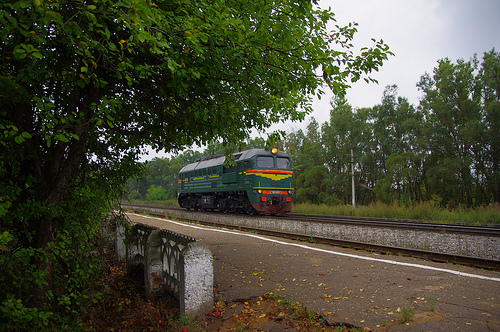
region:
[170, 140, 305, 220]
Locomotive of a freight train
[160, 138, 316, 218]
Locomotive for a passenger train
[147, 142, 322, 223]
Locomotive not pulling any cars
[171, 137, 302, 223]
Locomotive going down the tracks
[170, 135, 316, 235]
Locomotive heading toward the station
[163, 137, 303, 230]
Locomotive sitting idle on the tracks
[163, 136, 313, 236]
Locomotive moving through the countryside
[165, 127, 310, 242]
Locomotive of a railroad company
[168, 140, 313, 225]
Locomotive running in the daytime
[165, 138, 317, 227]
Locomotive carrying railroad employees home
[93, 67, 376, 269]
a train on a track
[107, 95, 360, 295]
a green train on a track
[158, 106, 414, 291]
a track with a green train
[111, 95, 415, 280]
a single train on a track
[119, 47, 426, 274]
a track with a single train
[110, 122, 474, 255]
a track with a green single train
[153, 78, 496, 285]
a single green train on track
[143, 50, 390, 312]
a train that is green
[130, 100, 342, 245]
a train on the tracks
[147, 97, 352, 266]
a single train on the tracks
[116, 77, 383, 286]
tracks with a train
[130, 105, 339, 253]
tracks with a single train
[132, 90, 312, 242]
a green train on the tracks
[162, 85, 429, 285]
tracks with a green train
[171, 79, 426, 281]
a green single train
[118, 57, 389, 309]
a green single train on tracks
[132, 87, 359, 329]
tracks with a green single train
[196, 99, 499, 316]
tracks surround with rocks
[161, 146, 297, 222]
a green train engine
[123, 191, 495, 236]
a set of railroad tracks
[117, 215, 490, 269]
a set of railroad tracks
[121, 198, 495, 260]
a stone railroad track bed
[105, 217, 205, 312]
a stone wall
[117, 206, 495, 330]
a paved brown street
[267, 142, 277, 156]
a train front headlight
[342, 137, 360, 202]
a tall metal pole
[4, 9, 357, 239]
a large tree in foreground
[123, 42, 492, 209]
a line of trees in distance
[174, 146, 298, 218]
engine with no cars on the tracks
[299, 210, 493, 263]
white and gray rock in between railroad tracks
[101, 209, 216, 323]
old white cement fence line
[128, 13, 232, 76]
thick green leaves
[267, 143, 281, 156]
headlight on front of train engine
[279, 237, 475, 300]
white line parellel to railroad tracks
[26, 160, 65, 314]
brown tree trunk behind leaves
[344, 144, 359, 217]
tall silver electric pole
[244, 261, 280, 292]
yellow leaves laying on cement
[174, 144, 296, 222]
green, yellow and orange engine